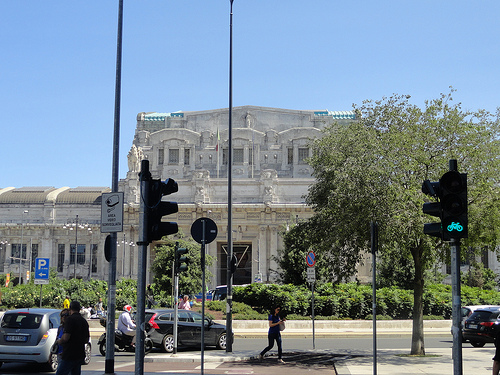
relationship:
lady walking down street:
[255, 302, 289, 367] [155, 331, 499, 352]